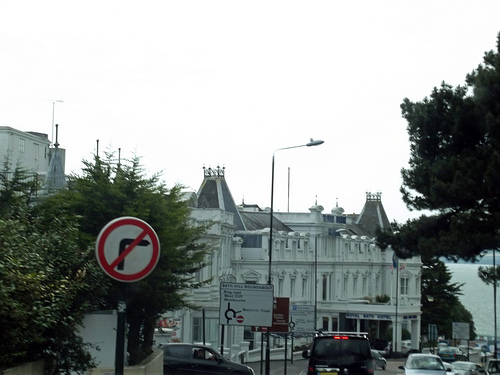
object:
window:
[341, 275, 348, 297]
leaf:
[16, 223, 23, 230]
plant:
[1, 148, 103, 374]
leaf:
[429, 161, 440, 168]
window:
[398, 287, 405, 295]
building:
[173, 165, 423, 364]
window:
[295, 236, 301, 248]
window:
[284, 237, 290, 249]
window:
[353, 276, 359, 294]